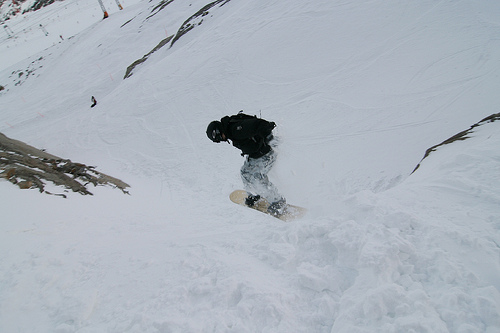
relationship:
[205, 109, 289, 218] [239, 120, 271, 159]
man wearing gear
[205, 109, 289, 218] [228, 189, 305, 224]
man on snowboard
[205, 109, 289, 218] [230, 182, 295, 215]
man on snowboard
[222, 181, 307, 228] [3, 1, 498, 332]
snowboard in snow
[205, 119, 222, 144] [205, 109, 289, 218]
helmet on man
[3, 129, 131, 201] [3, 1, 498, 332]
rocks in snow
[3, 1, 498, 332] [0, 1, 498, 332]
snow on ground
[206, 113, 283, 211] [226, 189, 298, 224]
man on snowboard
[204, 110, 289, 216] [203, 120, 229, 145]
man wearing helmet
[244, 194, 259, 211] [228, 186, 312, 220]
boot in snowboard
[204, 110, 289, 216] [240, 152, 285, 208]
man wearing pants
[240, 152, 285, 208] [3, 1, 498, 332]
pants covered with snow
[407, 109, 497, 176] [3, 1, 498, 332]
rock emerging from snow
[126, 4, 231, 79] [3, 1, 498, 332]
rock covered by snow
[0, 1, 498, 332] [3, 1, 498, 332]
ground covered by snow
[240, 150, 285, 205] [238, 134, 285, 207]
pants covered with snow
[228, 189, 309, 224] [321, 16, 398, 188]
snowboard laying on snow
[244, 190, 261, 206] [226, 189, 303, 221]
foot on snowboard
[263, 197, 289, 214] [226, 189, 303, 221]
foot on snowboard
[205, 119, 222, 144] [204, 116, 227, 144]
helmet on head